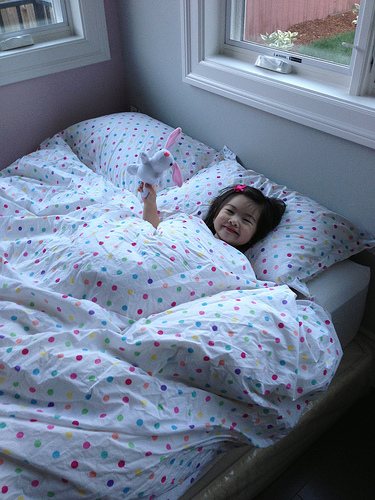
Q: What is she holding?
A: A stuffed animal.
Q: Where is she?
A: In a bed.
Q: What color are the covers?
A: Polka dotted.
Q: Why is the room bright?
A: Sunshine.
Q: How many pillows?
A: 2.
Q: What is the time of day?
A: Afternoon.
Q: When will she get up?
A: After a nap.